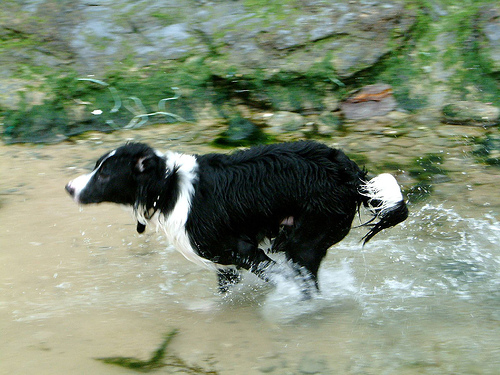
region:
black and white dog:
[25, 118, 412, 309]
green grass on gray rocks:
[398, 16, 429, 50]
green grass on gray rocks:
[198, 23, 229, 44]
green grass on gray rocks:
[275, 22, 317, 77]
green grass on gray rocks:
[92, 45, 160, 77]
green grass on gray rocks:
[405, 25, 435, 59]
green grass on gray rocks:
[40, 43, 101, 94]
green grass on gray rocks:
[150, 6, 184, 36]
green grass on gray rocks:
[347, 31, 409, 81]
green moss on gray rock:
[32, 29, 90, 69]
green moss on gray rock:
[91, 8, 133, 39]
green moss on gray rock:
[414, 16, 468, 63]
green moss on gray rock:
[408, 72, 430, 93]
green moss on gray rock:
[335, 31, 380, 53]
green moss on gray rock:
[270, 25, 310, 53]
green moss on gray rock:
[210, 29, 274, 61]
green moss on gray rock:
[148, 8, 203, 46]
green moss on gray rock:
[97, 45, 165, 86]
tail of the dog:
[360, 155, 419, 230]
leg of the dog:
[311, 267, 339, 292]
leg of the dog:
[259, 250, 290, 293]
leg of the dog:
[201, 265, 256, 300]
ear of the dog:
[147, 153, 172, 175]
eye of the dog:
[92, 163, 113, 184]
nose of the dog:
[59, 178, 86, 203]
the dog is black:
[222, 165, 294, 197]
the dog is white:
[167, 227, 183, 244]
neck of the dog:
[140, 153, 177, 215]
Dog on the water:
[52, 134, 422, 308]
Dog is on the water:
[60, 137, 417, 305]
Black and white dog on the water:
[61, 125, 416, 308]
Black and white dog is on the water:
[62, 134, 416, 306]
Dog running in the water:
[65, 136, 415, 307]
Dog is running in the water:
[61, 132, 415, 315]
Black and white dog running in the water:
[62, 135, 413, 312]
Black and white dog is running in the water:
[62, 130, 417, 307]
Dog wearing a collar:
[132, 145, 177, 235]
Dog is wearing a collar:
[130, 141, 179, 238]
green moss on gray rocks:
[21, 22, 69, 49]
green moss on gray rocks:
[5, 29, 45, 61]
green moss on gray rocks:
[392, 33, 460, 81]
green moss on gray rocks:
[325, 21, 366, 49]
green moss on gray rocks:
[272, 32, 323, 64]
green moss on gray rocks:
[202, 25, 292, 96]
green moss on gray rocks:
[155, 2, 216, 30]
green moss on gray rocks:
[90, 21, 174, 59]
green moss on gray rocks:
[41, 16, 113, 70]